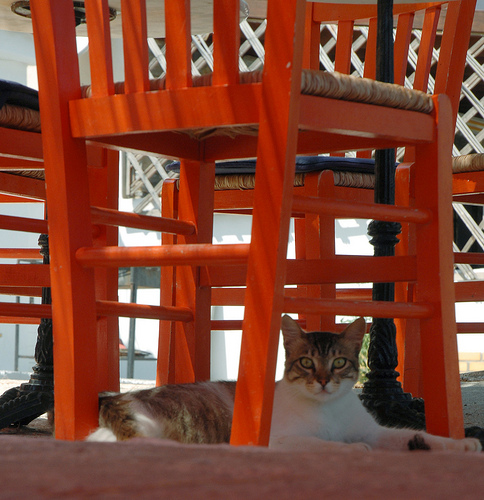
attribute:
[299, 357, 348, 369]
eyes — green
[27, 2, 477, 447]
chair — orange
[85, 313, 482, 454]
cat — lying, white, resting, brown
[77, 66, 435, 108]
cushion — brown, wicker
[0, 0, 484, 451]
post — metal, black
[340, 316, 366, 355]
ear — pointy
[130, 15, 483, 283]
fence — white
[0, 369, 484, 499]
ground — beige